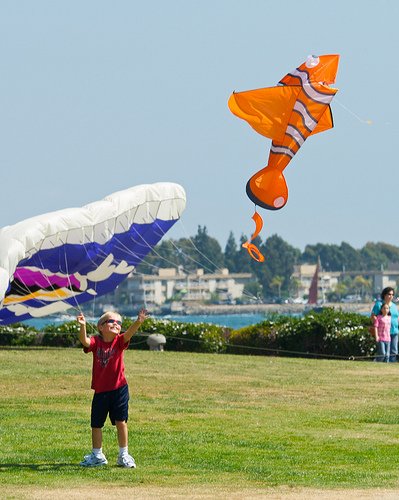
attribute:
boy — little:
[76, 307, 151, 468]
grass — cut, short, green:
[0, 345, 398, 500]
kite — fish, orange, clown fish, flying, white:
[227, 53, 341, 262]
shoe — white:
[78, 452, 109, 468]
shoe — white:
[116, 452, 137, 469]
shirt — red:
[83, 332, 130, 394]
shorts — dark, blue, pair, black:
[90, 384, 129, 428]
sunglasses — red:
[100, 318, 123, 326]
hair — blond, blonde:
[97, 311, 122, 336]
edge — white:
[0, 181, 187, 310]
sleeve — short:
[118, 332, 131, 350]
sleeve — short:
[83, 336, 96, 354]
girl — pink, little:
[372, 302, 392, 362]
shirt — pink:
[373, 314, 392, 342]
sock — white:
[118, 445, 128, 456]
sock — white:
[92, 447, 102, 457]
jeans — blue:
[377, 341, 391, 363]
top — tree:
[223, 231, 239, 275]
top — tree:
[341, 241, 363, 270]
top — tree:
[236, 232, 251, 273]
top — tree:
[135, 239, 180, 273]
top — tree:
[168, 236, 201, 268]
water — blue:
[20, 311, 371, 330]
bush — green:
[1, 322, 39, 347]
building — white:
[85, 264, 251, 310]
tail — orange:
[241, 166, 289, 263]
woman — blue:
[370, 287, 398, 362]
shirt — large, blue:
[371, 299, 398, 335]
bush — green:
[40, 319, 96, 348]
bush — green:
[122, 314, 233, 354]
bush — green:
[226, 305, 377, 361]